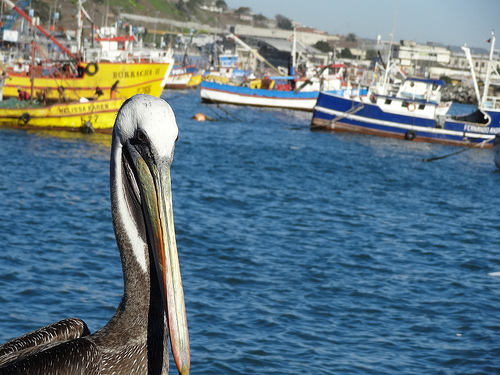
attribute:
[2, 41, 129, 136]
boat — anchored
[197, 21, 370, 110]
boat — anchored, blue, white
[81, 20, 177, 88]
boat — anchored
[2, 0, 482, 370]
coastal picture — beautiful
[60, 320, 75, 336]
feather — brown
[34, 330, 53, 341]
feather — brown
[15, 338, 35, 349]
feather — brown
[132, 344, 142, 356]
feather — brown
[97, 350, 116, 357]
feather — brown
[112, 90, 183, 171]
head — white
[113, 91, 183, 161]
head — white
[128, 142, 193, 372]
beak — long, yellow, very long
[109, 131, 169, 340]
neck — long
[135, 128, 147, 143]
eye — black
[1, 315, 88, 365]
wing — black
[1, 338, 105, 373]
wing — black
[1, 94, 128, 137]
paint — yellow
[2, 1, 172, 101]
boat — anchored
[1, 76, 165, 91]
line — red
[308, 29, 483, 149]
boat — blue, anchored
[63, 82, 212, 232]
head — white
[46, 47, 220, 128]
ships — yellow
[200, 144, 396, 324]
water — rippled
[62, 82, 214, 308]
bird — blue, white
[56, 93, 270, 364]
bird — white, grey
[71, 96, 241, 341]
bird — pelican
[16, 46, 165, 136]
boats — yellow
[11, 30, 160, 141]
sea — calm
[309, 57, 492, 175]
boat — blue, white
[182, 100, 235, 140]
buoy — floating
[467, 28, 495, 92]
pole — white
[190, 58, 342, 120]
boat — white, red, blue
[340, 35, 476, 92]
building — distant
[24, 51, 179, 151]
boats — yellow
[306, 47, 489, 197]
boat — blue